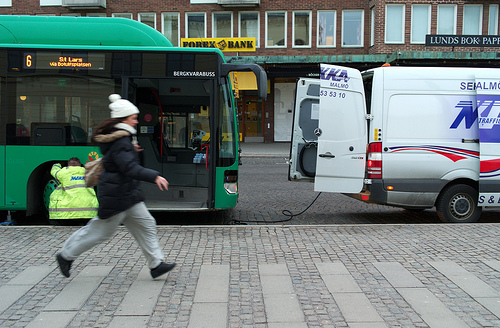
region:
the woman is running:
[59, 70, 197, 271]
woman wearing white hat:
[100, 90, 140, 126]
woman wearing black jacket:
[78, 125, 161, 207]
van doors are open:
[287, 50, 367, 192]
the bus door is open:
[130, 64, 257, 234]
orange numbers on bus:
[16, 38, 110, 75]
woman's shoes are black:
[41, 242, 206, 290]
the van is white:
[322, 45, 490, 221]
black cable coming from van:
[234, 165, 360, 245]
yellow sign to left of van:
[174, 17, 242, 60]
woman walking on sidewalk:
[52, 92, 177, 296]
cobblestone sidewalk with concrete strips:
[216, 232, 383, 326]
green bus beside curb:
[3, 14, 245, 229]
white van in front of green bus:
[275, 52, 497, 227]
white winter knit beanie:
[95, 87, 143, 129]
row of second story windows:
[197, 7, 413, 51]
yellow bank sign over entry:
[175, 34, 257, 59]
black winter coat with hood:
[87, 124, 162, 219]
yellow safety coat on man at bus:
[42, 157, 103, 222]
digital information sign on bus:
[19, 48, 116, 78]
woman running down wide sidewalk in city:
[26, 77, 269, 283]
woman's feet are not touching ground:
[41, 239, 189, 293]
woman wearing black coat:
[74, 124, 172, 215]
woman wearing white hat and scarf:
[89, 91, 145, 146]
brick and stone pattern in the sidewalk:
[173, 237, 445, 307]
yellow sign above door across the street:
[163, 14, 260, 61]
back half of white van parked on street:
[272, 46, 495, 233]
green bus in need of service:
[0, 9, 239, 215]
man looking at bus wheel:
[23, 143, 95, 225]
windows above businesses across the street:
[119, 5, 492, 65]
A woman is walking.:
[45, 81, 202, 299]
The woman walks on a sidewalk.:
[5, 82, 462, 327]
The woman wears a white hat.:
[100, 82, 144, 122]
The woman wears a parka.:
[75, 115, 167, 225]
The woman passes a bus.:
[5, 9, 255, 286]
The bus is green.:
[0, 10, 260, 231]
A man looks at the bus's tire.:
[27, 145, 103, 235]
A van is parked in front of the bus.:
[277, 48, 499, 228]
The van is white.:
[275, 48, 498, 220]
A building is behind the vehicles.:
[0, 1, 497, 100]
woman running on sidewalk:
[48, 84, 180, 290]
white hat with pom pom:
[103, 86, 144, 123]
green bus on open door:
[4, 23, 263, 218]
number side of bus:
[20, 48, 42, 73]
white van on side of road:
[280, 54, 493, 229]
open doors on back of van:
[281, 56, 378, 198]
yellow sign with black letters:
[178, 35, 257, 55]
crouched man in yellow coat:
[40, 153, 100, 225]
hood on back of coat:
[90, 123, 130, 157]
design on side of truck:
[393, 140, 470, 166]